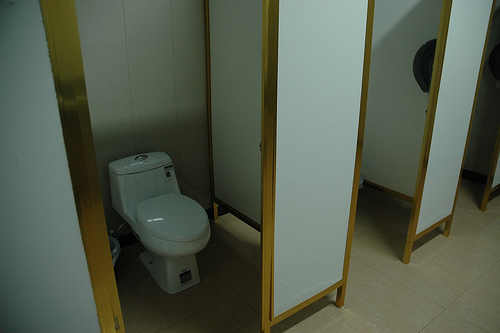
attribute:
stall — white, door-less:
[74, 1, 264, 331]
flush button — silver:
[135, 153, 149, 162]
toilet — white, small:
[109, 149, 212, 294]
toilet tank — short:
[108, 150, 181, 215]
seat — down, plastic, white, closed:
[134, 192, 211, 243]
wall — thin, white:
[207, 0, 262, 230]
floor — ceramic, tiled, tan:
[114, 180, 498, 332]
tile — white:
[125, 41, 176, 108]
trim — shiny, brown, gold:
[41, 1, 126, 331]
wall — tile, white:
[76, 0, 212, 248]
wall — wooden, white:
[261, 2, 376, 331]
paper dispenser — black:
[412, 38, 437, 93]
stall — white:
[332, 1, 496, 308]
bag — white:
[107, 234, 121, 268]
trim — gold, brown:
[259, 1, 282, 332]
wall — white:
[364, 1, 442, 201]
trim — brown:
[345, 0, 374, 234]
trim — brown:
[403, 0, 453, 265]